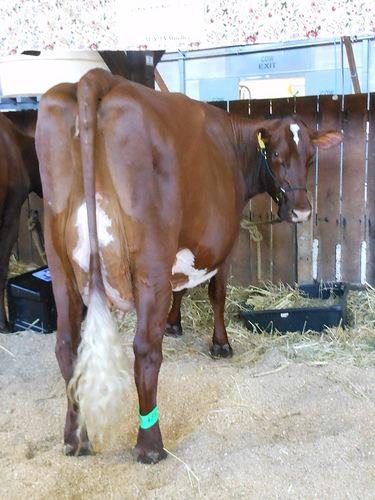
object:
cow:
[34, 66, 344, 464]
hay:
[244, 277, 340, 311]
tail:
[65, 66, 133, 457]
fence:
[10, 91, 374, 289]